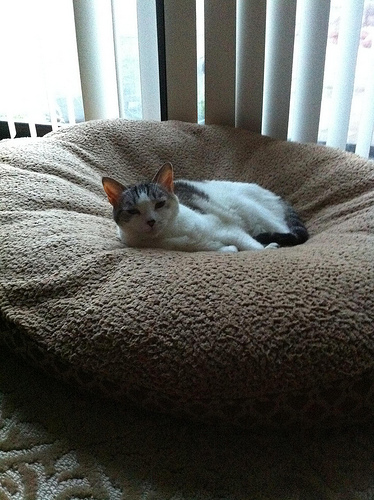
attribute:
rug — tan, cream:
[29, 401, 367, 485]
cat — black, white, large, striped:
[100, 162, 309, 254]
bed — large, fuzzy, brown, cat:
[4, 114, 368, 430]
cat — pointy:
[95, 157, 311, 256]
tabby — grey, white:
[100, 157, 312, 254]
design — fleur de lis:
[2, 434, 110, 497]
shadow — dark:
[75, 366, 370, 497]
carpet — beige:
[2, 364, 371, 497]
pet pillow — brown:
[4, 116, 371, 405]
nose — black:
[141, 213, 162, 229]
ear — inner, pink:
[98, 176, 123, 202]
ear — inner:
[151, 160, 180, 191]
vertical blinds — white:
[135, 18, 368, 147]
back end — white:
[241, 173, 306, 249]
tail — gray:
[252, 205, 309, 249]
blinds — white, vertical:
[72, 1, 369, 115]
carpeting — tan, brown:
[2, 364, 369, 496]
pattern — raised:
[2, 436, 107, 495]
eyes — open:
[123, 196, 169, 220]